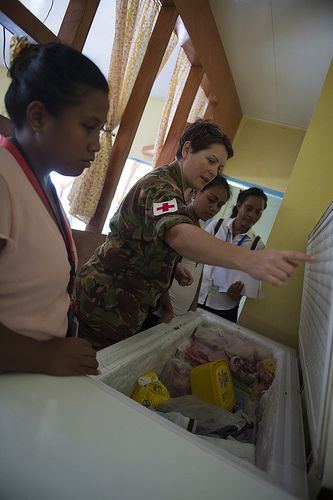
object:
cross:
[154, 202, 175, 213]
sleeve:
[141, 164, 191, 259]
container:
[190, 359, 236, 412]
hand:
[248, 248, 318, 288]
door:
[296, 200, 332, 487]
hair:
[173, 120, 235, 161]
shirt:
[198, 218, 268, 312]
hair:
[4, 36, 108, 127]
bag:
[129, 370, 172, 408]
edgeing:
[220, 174, 286, 199]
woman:
[73, 117, 316, 349]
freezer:
[84, 204, 332, 498]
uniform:
[73, 157, 197, 354]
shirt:
[0, 136, 79, 339]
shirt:
[154, 256, 204, 318]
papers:
[211, 264, 264, 300]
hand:
[227, 280, 248, 302]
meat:
[163, 357, 195, 400]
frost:
[255, 350, 280, 473]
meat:
[187, 340, 221, 364]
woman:
[2, 36, 109, 379]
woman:
[168, 170, 231, 315]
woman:
[196, 188, 268, 320]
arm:
[0, 324, 102, 382]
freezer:
[0, 375, 302, 500]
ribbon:
[9, 34, 28, 64]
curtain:
[66, 3, 165, 226]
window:
[50, 1, 164, 232]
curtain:
[152, 47, 193, 167]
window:
[103, 13, 200, 233]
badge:
[68, 313, 80, 341]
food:
[193, 323, 255, 361]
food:
[230, 355, 254, 384]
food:
[156, 394, 251, 442]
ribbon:
[0, 136, 78, 308]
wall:
[220, 61, 333, 351]